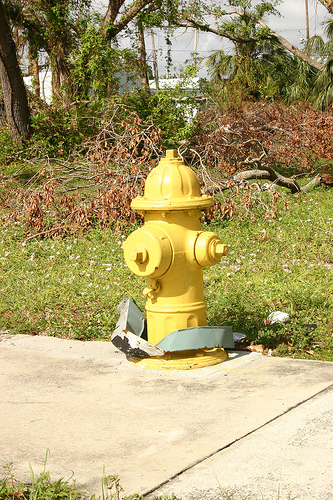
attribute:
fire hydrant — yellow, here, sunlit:
[137, 151, 225, 374]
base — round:
[131, 322, 230, 371]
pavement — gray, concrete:
[2, 329, 333, 500]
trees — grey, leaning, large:
[2, 3, 268, 131]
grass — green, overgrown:
[1, 131, 333, 356]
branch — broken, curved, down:
[20, 122, 323, 224]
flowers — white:
[14, 233, 126, 288]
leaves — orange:
[24, 6, 329, 97]